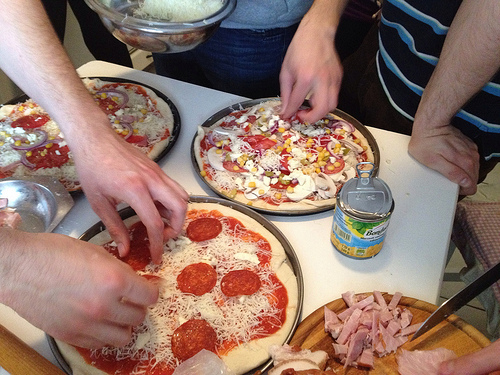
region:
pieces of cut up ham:
[307, 276, 427, 366]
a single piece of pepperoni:
[158, 307, 218, 369]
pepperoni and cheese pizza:
[135, 275, 279, 373]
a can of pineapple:
[306, 167, 416, 275]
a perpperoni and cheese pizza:
[91, 200, 277, 373]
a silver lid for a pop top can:
[337, 159, 403, 221]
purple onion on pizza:
[0, 75, 154, 201]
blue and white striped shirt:
[353, 8, 451, 147]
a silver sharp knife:
[361, 252, 488, 352]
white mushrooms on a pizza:
[281, 167, 344, 197]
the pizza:
[36, 143, 305, 365]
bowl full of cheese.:
[165, 5, 200, 12]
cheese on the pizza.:
[222, 309, 240, 326]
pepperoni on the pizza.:
[230, 272, 252, 287]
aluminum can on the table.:
[346, 220, 391, 255]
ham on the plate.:
[352, 311, 386, 338]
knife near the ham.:
[427, 272, 487, 328]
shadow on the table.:
[411, 216, 433, 258]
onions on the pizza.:
[23, 130, 42, 157]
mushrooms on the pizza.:
[307, 177, 327, 192]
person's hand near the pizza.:
[279, 47, 334, 119]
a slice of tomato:
[217, 268, 265, 296]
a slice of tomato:
[171, 261, 212, 293]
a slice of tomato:
[180, 211, 220, 241]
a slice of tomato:
[20, 145, 51, 165]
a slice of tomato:
[110, 230, 160, 270]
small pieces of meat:
[325, 290, 410, 365]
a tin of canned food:
[320, 165, 390, 260]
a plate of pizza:
[195, 95, 380, 210]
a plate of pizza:
[60, 190, 295, 370]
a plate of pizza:
[1, 65, 183, 177]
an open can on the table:
[321, 158, 413, 267]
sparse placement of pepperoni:
[164, 263, 261, 363]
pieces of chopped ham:
[319, 286, 423, 373]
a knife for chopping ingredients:
[409, 269, 498, 341]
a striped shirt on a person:
[370, 40, 492, 175]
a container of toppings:
[0, 170, 75, 232]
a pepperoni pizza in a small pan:
[50, 210, 298, 370]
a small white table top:
[0, 58, 462, 373]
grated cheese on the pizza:
[204, 236, 258, 268]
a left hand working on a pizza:
[258, 7, 360, 133]